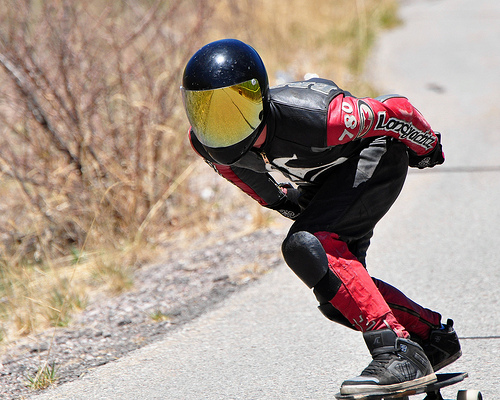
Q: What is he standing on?
A: Board.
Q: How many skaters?
A: 1.